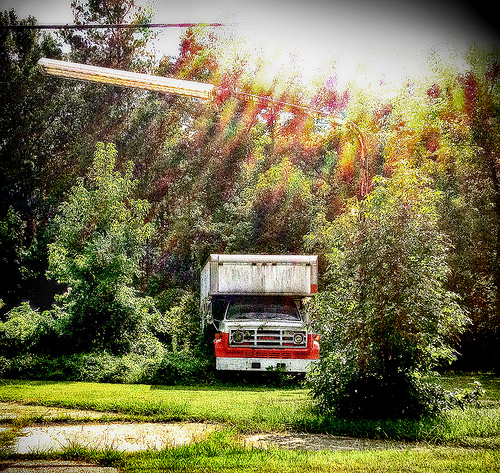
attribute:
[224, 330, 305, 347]
headlight — dirty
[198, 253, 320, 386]
truck — white, red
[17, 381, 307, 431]
grass — green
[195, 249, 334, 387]
truck — orange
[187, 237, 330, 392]
truck — big, orange, white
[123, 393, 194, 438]
grass — bright green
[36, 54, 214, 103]
light — long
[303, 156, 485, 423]
tree — green, leafy, medium